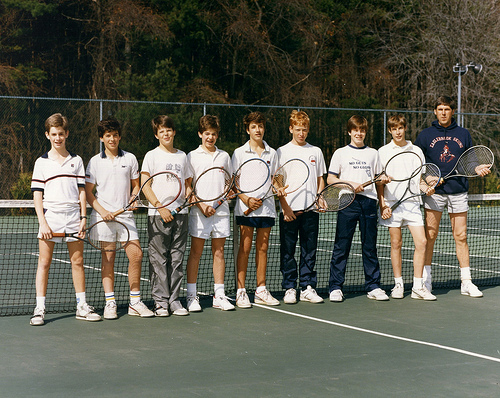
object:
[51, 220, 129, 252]
racket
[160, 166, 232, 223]
racket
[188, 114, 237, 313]
boy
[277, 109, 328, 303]
boy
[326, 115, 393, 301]
boy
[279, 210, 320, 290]
jeans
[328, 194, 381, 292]
jeans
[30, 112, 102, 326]
boy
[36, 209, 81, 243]
shorts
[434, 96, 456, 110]
hair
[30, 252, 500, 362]
line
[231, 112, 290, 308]
boy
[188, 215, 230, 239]
shorts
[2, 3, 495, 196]
trees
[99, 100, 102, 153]
pole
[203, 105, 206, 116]
pole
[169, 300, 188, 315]
shoes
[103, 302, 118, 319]
shoes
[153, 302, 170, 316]
shoes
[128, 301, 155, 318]
shoes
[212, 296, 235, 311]
shoes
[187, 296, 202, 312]
shoes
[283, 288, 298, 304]
shoes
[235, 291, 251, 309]
shoes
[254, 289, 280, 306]
shoes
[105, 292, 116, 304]
socks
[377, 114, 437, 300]
boy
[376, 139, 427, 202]
shirt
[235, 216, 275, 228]
shorts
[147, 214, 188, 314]
pants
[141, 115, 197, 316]
boy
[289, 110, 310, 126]
hair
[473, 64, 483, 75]
light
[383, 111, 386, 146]
pole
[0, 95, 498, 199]
fence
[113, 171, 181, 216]
racket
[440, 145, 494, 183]
racket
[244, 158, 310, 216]
racket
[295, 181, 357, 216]
racket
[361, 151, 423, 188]
racket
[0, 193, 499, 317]
net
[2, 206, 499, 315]
strings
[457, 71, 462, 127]
pole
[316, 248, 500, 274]
lines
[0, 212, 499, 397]
court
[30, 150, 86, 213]
shirt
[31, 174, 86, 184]
stripe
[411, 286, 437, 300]
sneaker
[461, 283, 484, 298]
sneaker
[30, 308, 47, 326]
foot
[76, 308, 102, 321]
foot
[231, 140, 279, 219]
shirt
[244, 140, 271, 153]
collar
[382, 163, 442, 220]
racket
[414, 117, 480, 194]
sweatshirt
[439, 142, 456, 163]
emblem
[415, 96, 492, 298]
man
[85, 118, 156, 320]
boy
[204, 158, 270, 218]
racket